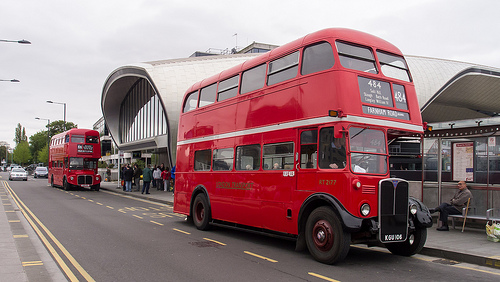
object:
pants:
[429, 202, 463, 227]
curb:
[99, 174, 175, 206]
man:
[123, 166, 134, 192]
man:
[427, 180, 474, 231]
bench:
[421, 185, 499, 232]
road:
[3, 156, 499, 280]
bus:
[45, 122, 101, 188]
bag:
[486, 219, 498, 241]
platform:
[422, 219, 498, 259]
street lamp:
[2, 37, 32, 44]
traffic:
[10, 129, 103, 186]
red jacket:
[161, 170, 172, 181]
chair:
[448, 203, 498, 233]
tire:
[303, 202, 353, 262]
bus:
[171, 28, 432, 266]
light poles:
[31, 99, 68, 164]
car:
[9, 168, 30, 181]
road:
[2, 177, 149, 267]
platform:
[101, 138, 172, 205]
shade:
[100, 61, 170, 145]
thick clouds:
[32, 15, 87, 81]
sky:
[6, 2, 246, 95]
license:
[384, 233, 403, 241]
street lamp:
[44, 99, 66, 124]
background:
[2, 1, 122, 183]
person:
[103, 167, 112, 182]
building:
[93, 39, 500, 235]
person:
[132, 165, 143, 192]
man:
[140, 166, 153, 194]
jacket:
[139, 168, 155, 182]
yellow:
[100, 197, 159, 237]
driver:
[326, 138, 350, 168]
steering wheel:
[350, 154, 372, 164]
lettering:
[118, 201, 186, 220]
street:
[22, 172, 270, 279]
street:
[1, 165, 484, 279]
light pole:
[0, 78, 20, 83]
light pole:
[0, 38, 29, 45]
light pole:
[44, 99, 66, 130]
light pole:
[34, 117, 50, 139]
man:
[160, 166, 171, 192]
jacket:
[122, 168, 134, 181]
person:
[152, 166, 163, 191]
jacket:
[152, 168, 162, 180]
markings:
[47, 178, 330, 279]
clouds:
[256, 0, 323, 33]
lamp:
[16, 38, 33, 46]